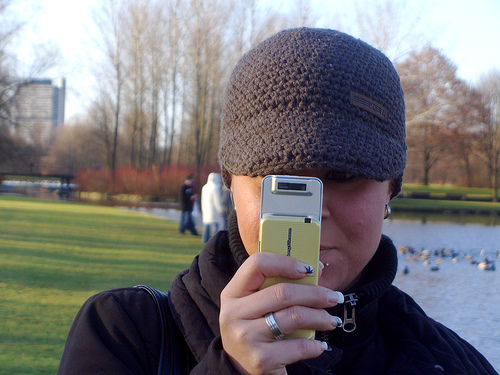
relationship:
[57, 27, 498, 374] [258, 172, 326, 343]
woman holding phone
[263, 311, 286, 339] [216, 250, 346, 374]
ring on hand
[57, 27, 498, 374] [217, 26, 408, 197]
woman wearing cap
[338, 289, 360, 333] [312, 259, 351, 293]
zipper near chin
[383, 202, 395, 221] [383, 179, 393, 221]
earring in ear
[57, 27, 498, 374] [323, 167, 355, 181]
woman has eye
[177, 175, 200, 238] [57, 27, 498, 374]
man behind woman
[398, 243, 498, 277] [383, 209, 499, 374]
ducks in pond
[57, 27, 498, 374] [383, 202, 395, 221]
woman wearing earring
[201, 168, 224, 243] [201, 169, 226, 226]
person wearing hoodie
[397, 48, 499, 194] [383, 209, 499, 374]
trees next to pond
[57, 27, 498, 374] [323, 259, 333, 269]
woman has lip piercing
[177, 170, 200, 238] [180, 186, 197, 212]
man wearing shirt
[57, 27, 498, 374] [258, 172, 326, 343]
woman taking picture with phone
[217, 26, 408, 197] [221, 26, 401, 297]
cap on head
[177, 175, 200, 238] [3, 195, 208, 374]
man standing on grass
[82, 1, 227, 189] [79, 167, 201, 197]
trees behind bushes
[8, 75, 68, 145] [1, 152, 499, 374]
building behind park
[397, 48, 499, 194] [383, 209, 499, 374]
trees behind pond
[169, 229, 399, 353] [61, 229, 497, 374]
collar on jacket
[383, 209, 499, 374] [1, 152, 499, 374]
pond in park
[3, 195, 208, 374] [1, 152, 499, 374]
grass in park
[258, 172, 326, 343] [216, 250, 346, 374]
phone in hand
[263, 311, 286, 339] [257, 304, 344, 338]
ring on finger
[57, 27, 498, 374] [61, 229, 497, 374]
woman wearing jacket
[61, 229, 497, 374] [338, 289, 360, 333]
jacket has zipper